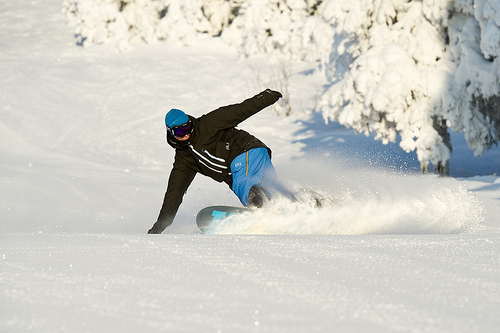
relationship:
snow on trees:
[399, 125, 429, 161] [316, 20, 479, 180]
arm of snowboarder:
[140, 157, 198, 240] [192, 203, 274, 235]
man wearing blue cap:
[147, 88, 289, 233] [162, 105, 192, 128]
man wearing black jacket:
[147, 88, 289, 233] [156, 88, 272, 186]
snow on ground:
[2, 0, 498, 330] [1, 1, 493, 331]